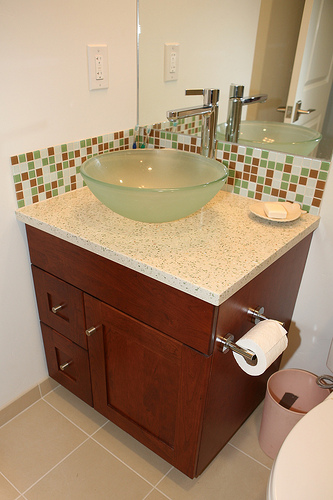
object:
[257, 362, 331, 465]
basket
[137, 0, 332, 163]
mirror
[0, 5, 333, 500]
bathroom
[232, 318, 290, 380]
paper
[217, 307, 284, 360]
dispenser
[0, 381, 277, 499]
floor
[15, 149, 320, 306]
countertop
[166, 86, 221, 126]
faucet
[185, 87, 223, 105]
handle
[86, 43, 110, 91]
outlet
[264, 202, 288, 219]
soap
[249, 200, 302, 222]
dish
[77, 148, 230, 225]
sink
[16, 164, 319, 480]
vanity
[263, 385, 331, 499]
toilet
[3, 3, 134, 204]
wall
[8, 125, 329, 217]
backsplash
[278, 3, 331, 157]
reflection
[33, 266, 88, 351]
drawer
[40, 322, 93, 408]
drawer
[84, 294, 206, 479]
door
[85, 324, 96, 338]
knobs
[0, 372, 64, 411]
border